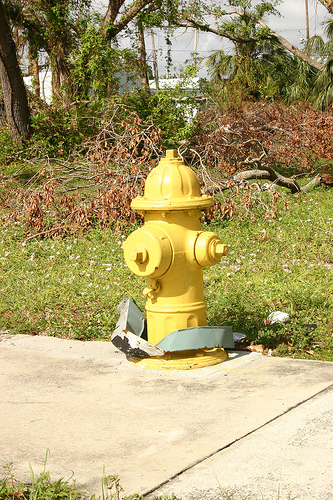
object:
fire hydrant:
[121, 150, 229, 369]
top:
[144, 148, 200, 196]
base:
[131, 323, 226, 371]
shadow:
[216, 309, 306, 344]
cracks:
[134, 380, 332, 497]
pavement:
[0, 329, 333, 500]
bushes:
[8, 94, 333, 152]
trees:
[2, 3, 268, 131]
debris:
[25, 114, 296, 315]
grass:
[1, 131, 333, 356]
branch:
[0, 122, 323, 224]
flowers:
[14, 233, 121, 288]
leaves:
[24, 6, 329, 97]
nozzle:
[123, 230, 163, 277]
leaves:
[23, 107, 225, 221]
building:
[32, 61, 216, 116]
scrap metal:
[111, 294, 234, 364]